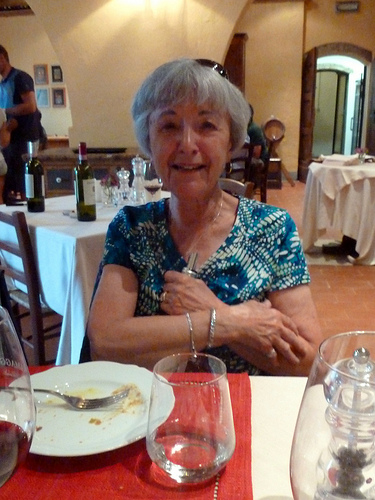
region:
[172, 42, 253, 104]
Sunglasses on top of woman's head.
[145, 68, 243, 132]
Woman has gray hair on head.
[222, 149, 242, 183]
Woman wearing hoop earrings.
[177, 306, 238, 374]
Silver bracelets on woman's wrist.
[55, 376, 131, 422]
Silver fork on white plate.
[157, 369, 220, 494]
Clear glass sitting on table.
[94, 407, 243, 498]
Red place mat sitting on table.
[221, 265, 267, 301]
Woman wearing blue and white shirt.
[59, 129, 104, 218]
Bottle of wine on table behind woman.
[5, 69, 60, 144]
Person wearing dark shirt.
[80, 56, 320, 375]
a woman looking at the camera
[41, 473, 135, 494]
a red cloth placemat on the table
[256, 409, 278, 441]
white surface of the table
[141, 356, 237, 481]
empty clear glass on the table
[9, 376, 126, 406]
grey metal fork on the plate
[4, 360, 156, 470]
round white plate on the placemat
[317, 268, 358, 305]
red brick surface of the floor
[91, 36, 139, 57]
yellow stucco surface of the wall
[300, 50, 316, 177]
broown wooden door of the room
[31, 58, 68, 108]
several pictures on the wall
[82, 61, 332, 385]
Woman at a table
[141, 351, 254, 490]
Glass on a table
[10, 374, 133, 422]
Fork on a plate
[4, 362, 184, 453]
White plate on a table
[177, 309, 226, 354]
Bracelets on a wrist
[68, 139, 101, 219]
Wine bottle on a table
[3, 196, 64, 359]
Wood chair at a table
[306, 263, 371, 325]
Light reflecting off of a floor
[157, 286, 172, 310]
Ring on a woman's finger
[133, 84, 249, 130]
Gray hair on a woman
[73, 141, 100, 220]
wine bottle on the table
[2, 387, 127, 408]
metal fork on a plate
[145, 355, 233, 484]
small glass is empty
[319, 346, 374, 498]
pepper cracker on the table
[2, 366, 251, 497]
red place mat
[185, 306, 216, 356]
silver bracelets on her wrist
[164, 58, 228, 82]
sunglasses on the woman's head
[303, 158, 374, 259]
long white table cloths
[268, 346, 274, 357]
ring on her pinkie finger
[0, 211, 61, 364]
wooden chair is empty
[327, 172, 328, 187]
part of a table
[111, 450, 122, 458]
edge of a plate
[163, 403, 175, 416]
edge of a cup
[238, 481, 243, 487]
part of a cloth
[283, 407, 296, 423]
part of a table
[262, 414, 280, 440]
edge of a table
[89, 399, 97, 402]
part of a fork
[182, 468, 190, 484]
bottom of a cup